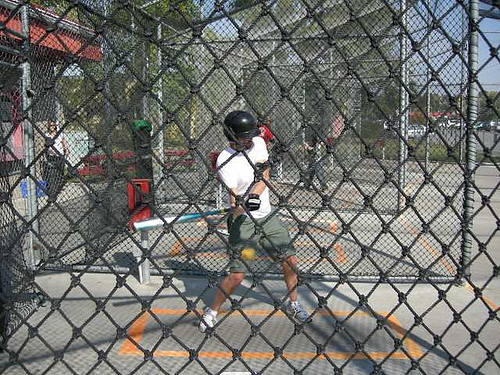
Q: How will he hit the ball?
A: With a bat.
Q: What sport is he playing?
A: Baseball.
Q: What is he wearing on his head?
A: A helmet.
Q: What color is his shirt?
A: White.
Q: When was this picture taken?
A: In the daytime.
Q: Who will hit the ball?
A: The boy.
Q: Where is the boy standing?
A: Inside the yellow box.